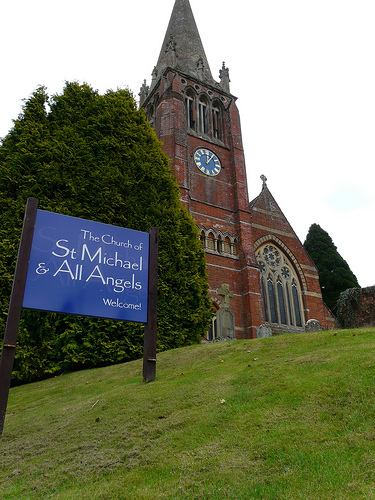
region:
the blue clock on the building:
[189, 142, 225, 177]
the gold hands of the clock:
[192, 146, 222, 181]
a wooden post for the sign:
[141, 227, 161, 387]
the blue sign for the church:
[24, 207, 150, 321]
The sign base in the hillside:
[0, 347, 181, 499]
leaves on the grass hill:
[201, 347, 262, 403]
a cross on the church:
[255, 172, 272, 190]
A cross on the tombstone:
[216, 278, 237, 304]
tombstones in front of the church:
[214, 309, 327, 349]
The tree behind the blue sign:
[0, 78, 211, 375]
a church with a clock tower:
[134, 0, 340, 341]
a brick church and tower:
[137, 0, 342, 342]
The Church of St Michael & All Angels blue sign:
[1, 195, 157, 436]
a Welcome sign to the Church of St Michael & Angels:
[1, 195, 160, 431]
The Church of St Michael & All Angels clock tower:
[137, 0, 264, 341]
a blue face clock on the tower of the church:
[191, 145, 222, 177]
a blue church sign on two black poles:
[0, 196, 158, 436]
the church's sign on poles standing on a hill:
[1, 195, 373, 497]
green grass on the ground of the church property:
[192, 346, 367, 493]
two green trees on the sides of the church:
[0, 0, 362, 388]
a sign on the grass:
[2, 175, 188, 379]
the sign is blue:
[17, 188, 174, 349]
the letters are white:
[13, 203, 154, 324]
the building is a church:
[107, 7, 347, 363]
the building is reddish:
[155, 97, 270, 349]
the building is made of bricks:
[140, 96, 277, 329]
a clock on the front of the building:
[166, 135, 231, 190]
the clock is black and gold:
[165, 143, 233, 180]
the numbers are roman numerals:
[182, 142, 224, 178]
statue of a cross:
[201, 272, 247, 309]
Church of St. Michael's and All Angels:
[138, 0, 369, 332]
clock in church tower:
[188, 144, 223, 176]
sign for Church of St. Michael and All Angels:
[22, 205, 159, 386]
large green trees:
[2, 80, 208, 389]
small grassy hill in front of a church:
[6, 325, 372, 496]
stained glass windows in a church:
[248, 234, 309, 337]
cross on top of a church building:
[258, 173, 270, 189]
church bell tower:
[145, 2, 262, 344]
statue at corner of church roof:
[163, 34, 180, 70]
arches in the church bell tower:
[179, 80, 234, 149]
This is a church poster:
[3, 187, 182, 472]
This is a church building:
[154, 2, 269, 366]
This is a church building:
[243, 159, 348, 349]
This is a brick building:
[248, 156, 335, 338]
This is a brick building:
[137, 0, 269, 348]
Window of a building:
[260, 273, 269, 327]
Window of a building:
[266, 271, 281, 324]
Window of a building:
[275, 274, 288, 325]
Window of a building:
[291, 277, 307, 331]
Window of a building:
[208, 223, 217, 253]